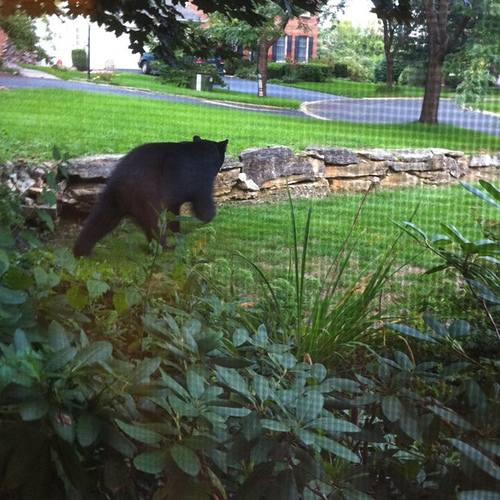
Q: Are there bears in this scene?
A: Yes, there is a bear.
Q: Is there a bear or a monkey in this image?
A: Yes, there is a bear.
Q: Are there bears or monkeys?
A: Yes, there is a bear.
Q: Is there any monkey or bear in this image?
A: Yes, there is a bear.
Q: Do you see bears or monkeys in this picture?
A: Yes, there is a bear.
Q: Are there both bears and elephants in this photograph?
A: No, there is a bear but no elephants.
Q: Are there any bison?
A: No, there are no bison.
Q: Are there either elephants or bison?
A: No, there are no bison or elephants.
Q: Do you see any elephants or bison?
A: No, there are no bison or elephants.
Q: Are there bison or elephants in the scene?
A: No, there are no bison or elephants.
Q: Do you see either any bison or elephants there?
A: No, there are no bison or elephants.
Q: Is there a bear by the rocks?
A: Yes, there is a bear by the rocks.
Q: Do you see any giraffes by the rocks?
A: No, there is a bear by the rocks.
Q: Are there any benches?
A: No, there are no benches.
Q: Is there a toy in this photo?
A: No, there are no toys.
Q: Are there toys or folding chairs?
A: No, there are no toys or folding chairs.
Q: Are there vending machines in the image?
A: No, there are no vending machines.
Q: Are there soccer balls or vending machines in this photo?
A: No, there are no vending machines or soccer balls.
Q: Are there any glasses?
A: No, there are no glasses.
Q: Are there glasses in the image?
A: No, there are no glasses.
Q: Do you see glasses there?
A: No, there are no glasses.